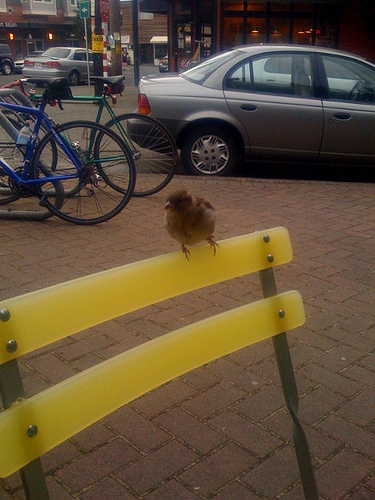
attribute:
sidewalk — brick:
[1, 185, 373, 497]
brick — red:
[1, 172, 372, 490]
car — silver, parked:
[124, 41, 373, 181]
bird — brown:
[134, 158, 244, 275]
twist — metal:
[270, 330, 318, 498]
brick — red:
[293, 201, 336, 227]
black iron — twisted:
[267, 339, 333, 481]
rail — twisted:
[3, 223, 304, 480]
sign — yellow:
[89, 34, 104, 53]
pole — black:
[92, 0, 103, 97]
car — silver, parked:
[20, 43, 110, 86]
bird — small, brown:
[161, 188, 219, 261]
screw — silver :
[1, 310, 10, 320]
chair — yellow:
[12, 229, 330, 476]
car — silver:
[22, 42, 103, 93]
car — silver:
[155, 50, 174, 71]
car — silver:
[13, 50, 46, 69]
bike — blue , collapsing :
[1, 77, 134, 226]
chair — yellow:
[0, 226, 309, 478]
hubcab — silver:
[191, 132, 230, 172]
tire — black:
[180, 123, 240, 178]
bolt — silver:
[27, 423, 38, 436]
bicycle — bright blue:
[0, 72, 140, 234]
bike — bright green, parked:
[14, 70, 181, 200]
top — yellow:
[0, 225, 306, 479]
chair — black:
[5, 208, 341, 499]